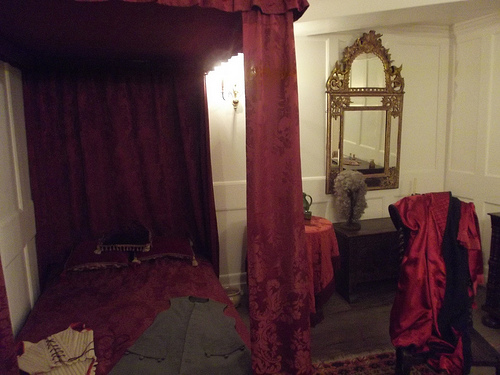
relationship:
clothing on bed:
[16, 322, 95, 373] [13, 230, 252, 373]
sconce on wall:
[211, 68, 265, 150] [233, 27, 491, 207]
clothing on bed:
[108, 289, 252, 369] [12, 249, 257, 374]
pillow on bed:
[97, 232, 152, 252] [1, 3, 306, 373]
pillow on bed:
[97, 225, 151, 243] [32, 250, 229, 371]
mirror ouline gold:
[323, 27, 405, 192] [385, 67, 404, 182]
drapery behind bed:
[26, 61, 219, 293] [15, 256, 210, 373]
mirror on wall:
[323, 27, 405, 192] [282, 6, 458, 271]